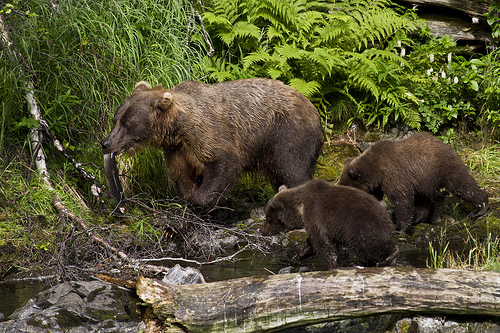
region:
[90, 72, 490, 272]
A mother bear and her cubs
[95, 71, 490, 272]
A mother bear and her cubs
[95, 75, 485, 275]
A mother bear and her cubs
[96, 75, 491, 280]
A mother bear and her cubs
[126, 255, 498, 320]
Dried up log floating in a river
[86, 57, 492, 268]
Mother bear and two cubs walking in the river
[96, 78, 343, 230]
Mother bear with a fish in her mouth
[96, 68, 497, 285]
Bear getting food for her cubs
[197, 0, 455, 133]
Fern bush beside the river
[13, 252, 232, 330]
Big rocks sitting in the river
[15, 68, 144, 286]
Fallen tree branch in the river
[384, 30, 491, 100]
Bush with white flowers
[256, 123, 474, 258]
Baby cubs waiting for their food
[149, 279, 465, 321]
log is in the water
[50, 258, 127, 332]
rock is grey in color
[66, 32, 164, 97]
plants are green in color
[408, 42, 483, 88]
the flower petals are white in color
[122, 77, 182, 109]
the horns are grey in coor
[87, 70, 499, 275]
An adult bear ready to feed her cubs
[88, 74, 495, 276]
An adult bear ready to feed her cubs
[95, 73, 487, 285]
An adult bear ready to feed her cubs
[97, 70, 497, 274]
An adult bear ready to feed her cubs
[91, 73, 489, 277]
An adult bear ready to feed her cubs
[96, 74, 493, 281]
An adult bear ready to feed her cubs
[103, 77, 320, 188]
one large bear walking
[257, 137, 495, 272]
two baby cubs following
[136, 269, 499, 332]
a wood long by the water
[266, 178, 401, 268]
bear is sitting on the ground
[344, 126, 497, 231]
bear's face is in the ground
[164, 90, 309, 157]
bear's fur is brown and black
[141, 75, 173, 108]
top of ears are white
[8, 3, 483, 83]
green leafy vegetation in the back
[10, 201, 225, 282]
broken tree branch across the river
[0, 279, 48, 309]
water near the logs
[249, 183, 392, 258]
An animal in a field.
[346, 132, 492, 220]
An animal in a field.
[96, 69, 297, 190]
An animal in a field.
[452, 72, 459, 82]
A flower on a stem.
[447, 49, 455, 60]
A flower on a stem.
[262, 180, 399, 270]
Baby bear sitting on a log.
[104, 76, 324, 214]
Adult bear walking through water.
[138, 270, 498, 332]
Large log on top of water.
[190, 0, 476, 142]
Large ferns behind bears.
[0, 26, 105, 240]
Long white stick next to adult bear.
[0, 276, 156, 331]
Large rock wet with water.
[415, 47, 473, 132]
White flowers next to a fern.